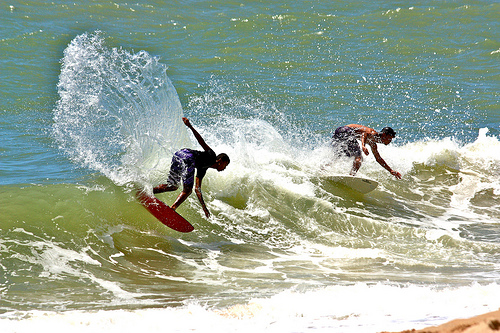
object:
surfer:
[152, 117, 231, 219]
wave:
[2, 127, 496, 291]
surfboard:
[135, 190, 195, 233]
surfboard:
[324, 175, 379, 194]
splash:
[50, 30, 192, 187]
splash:
[237, 118, 290, 155]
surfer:
[320, 123, 402, 179]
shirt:
[192, 149, 217, 179]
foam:
[35, 244, 104, 272]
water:
[1, 3, 500, 333]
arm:
[188, 126, 212, 151]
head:
[216, 153, 230, 173]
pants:
[167, 148, 196, 193]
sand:
[443, 318, 499, 333]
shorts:
[332, 126, 361, 157]